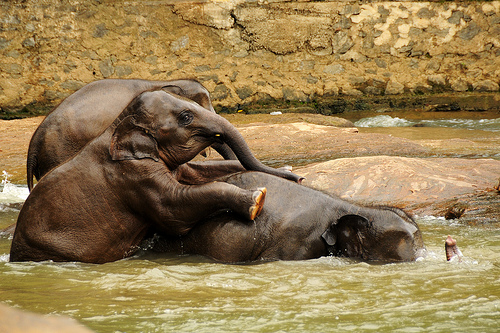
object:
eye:
[179, 112, 191, 123]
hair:
[302, 185, 419, 231]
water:
[352, 109, 500, 159]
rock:
[0, 0, 497, 120]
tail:
[25, 130, 42, 194]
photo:
[0, 0, 500, 333]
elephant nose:
[445, 235, 463, 262]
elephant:
[9, 89, 304, 264]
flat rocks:
[0, 117, 500, 223]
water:
[0, 171, 500, 333]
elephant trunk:
[222, 121, 307, 185]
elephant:
[152, 171, 459, 266]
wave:
[354, 114, 415, 127]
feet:
[241, 187, 267, 222]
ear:
[109, 115, 160, 162]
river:
[0, 109, 500, 333]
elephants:
[8, 78, 462, 265]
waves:
[138, 270, 311, 333]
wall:
[91, 46, 498, 144]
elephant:
[26, 78, 236, 192]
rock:
[273, 157, 500, 220]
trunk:
[201, 106, 331, 187]